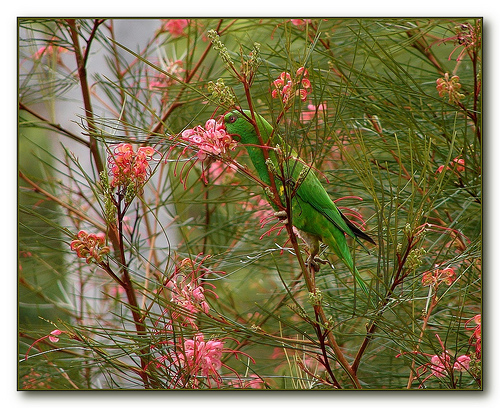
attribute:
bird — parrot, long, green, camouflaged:
[218, 118, 372, 267]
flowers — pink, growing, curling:
[77, 54, 397, 271]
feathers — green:
[299, 175, 362, 241]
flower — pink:
[100, 140, 146, 197]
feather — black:
[319, 226, 379, 304]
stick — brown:
[65, 51, 99, 167]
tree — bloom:
[32, 35, 360, 333]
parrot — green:
[208, 102, 311, 223]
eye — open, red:
[221, 111, 240, 122]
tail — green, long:
[321, 225, 384, 311]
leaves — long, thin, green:
[134, 309, 315, 378]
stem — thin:
[109, 227, 159, 372]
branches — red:
[107, 202, 164, 382]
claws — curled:
[304, 259, 324, 272]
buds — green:
[205, 30, 240, 66]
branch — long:
[159, 46, 201, 141]